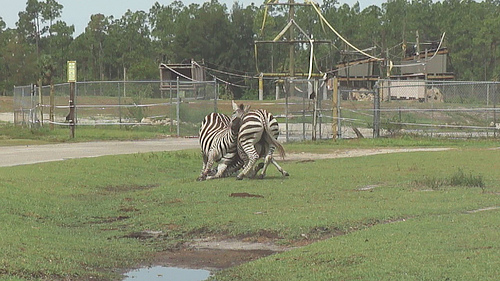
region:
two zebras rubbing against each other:
[197, 103, 275, 171]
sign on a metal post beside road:
[56, 51, 82, 141]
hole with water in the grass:
[114, 225, 248, 280]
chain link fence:
[90, 73, 178, 133]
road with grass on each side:
[4, 113, 154, 170]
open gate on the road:
[281, 79, 324, 139]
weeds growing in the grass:
[426, 158, 485, 205]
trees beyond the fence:
[46, 19, 176, 91]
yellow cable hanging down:
[311, 5, 383, 71]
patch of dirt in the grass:
[321, 145, 439, 156]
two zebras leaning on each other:
[197, 94, 289, 185]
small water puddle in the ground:
[103, 260, 228, 279]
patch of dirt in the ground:
[150, 219, 317, 271]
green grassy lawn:
[17, 163, 152, 270]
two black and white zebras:
[196, 97, 292, 185]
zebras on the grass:
[197, 100, 296, 182]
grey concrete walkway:
[10, 127, 177, 164]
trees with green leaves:
[16, 1, 206, 64]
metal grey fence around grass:
[9, 78, 209, 140]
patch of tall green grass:
[446, 158, 489, 195]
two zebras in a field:
[161, 85, 329, 191]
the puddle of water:
[117, 248, 197, 278]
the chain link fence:
[22, 76, 498, 122]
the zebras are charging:
[165, 112, 337, 185]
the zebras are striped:
[167, 80, 313, 187]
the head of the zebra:
[214, 98, 244, 133]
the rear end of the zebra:
[242, 108, 287, 160]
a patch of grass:
[420, 164, 496, 200]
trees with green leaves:
[81, 15, 263, 53]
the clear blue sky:
[79, 3, 140, 13]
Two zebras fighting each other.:
[193, 100, 288, 180]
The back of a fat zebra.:
[235, 107, 285, 177]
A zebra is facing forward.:
[198, 98, 251, 180]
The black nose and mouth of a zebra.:
[229, 115, 242, 132]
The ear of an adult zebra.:
[230, 100, 239, 112]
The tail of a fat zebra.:
[262, 114, 287, 158]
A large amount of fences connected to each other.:
[12, 81, 498, 137]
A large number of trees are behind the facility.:
[0, 0, 499, 100]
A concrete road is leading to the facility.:
[0, 133, 198, 164]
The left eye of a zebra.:
[231, 107, 239, 114]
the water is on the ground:
[105, 226, 284, 276]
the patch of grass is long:
[413, 154, 492, 200]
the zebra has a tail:
[256, 118, 289, 158]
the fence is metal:
[92, 74, 131, 128]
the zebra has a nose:
[226, 110, 242, 131]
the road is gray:
[24, 143, 67, 157]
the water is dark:
[155, 250, 207, 279]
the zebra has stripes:
[199, 117, 224, 145]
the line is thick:
[310, 10, 363, 47]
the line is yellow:
[317, 12, 368, 52]